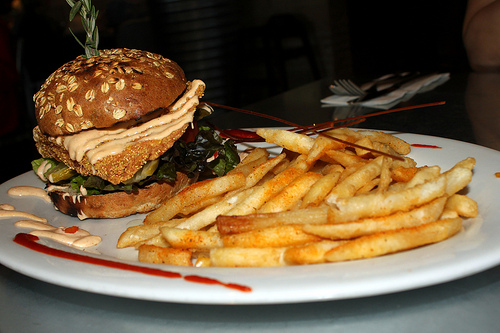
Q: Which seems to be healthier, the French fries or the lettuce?
A: The lettuce is healthier than the French fries.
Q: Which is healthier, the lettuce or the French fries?
A: The lettuce is healthier than the French fries.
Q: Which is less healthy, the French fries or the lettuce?
A: The French fries is less healthy than the lettuce.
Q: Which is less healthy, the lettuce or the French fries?
A: The French fries is less healthy than the lettuce.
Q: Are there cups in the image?
A: No, there are no cups.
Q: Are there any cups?
A: No, there are no cups.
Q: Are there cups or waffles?
A: No, there are no cups or waffles.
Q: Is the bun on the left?
A: Yes, the bun is on the left of the image.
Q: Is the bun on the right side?
A: No, the bun is on the left of the image.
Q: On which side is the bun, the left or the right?
A: The bun is on the left of the image.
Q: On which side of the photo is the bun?
A: The bun is on the left of the image.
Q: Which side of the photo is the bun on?
A: The bun is on the left of the image.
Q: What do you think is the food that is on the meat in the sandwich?
A: The food is a bun.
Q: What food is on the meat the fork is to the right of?
A: The food is a bun.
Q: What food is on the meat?
A: The food is a bun.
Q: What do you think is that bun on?
A: The bun is on the meat.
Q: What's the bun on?
A: The bun is on the meat.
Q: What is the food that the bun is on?
A: The food is meat.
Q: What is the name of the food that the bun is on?
A: The food is meat.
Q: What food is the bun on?
A: The bun is on the meat.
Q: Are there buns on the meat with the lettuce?
A: Yes, there is a bun on the meat.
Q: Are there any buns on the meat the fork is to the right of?
A: Yes, there is a bun on the meat.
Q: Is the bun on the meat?
A: Yes, the bun is on the meat.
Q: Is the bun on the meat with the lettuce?
A: Yes, the bun is on the meat.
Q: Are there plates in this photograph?
A: Yes, there is a plate.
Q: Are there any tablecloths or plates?
A: Yes, there is a plate.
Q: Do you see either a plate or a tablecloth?
A: Yes, there is a plate.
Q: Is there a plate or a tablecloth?
A: Yes, there is a plate.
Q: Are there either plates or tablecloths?
A: Yes, there is a plate.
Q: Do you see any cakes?
A: No, there are no cakes.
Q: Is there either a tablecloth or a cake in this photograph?
A: No, there are no cakes or tablecloths.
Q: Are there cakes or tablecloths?
A: No, there are no cakes or tablecloths.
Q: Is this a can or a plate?
A: This is a plate.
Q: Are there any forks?
A: Yes, there is a fork.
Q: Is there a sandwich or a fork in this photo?
A: Yes, there is a fork.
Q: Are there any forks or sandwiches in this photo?
A: Yes, there is a fork.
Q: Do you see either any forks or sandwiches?
A: Yes, there is a fork.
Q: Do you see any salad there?
A: No, there is no salad.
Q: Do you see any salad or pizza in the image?
A: No, there are no salad or pizzas.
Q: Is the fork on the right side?
A: Yes, the fork is on the right of the image.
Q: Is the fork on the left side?
A: No, the fork is on the right of the image.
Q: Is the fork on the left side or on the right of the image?
A: The fork is on the right of the image.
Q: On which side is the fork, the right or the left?
A: The fork is on the right of the image.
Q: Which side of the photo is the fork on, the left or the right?
A: The fork is on the right of the image.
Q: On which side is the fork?
A: The fork is on the right of the image.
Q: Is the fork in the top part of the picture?
A: Yes, the fork is in the top of the image.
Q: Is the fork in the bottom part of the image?
A: No, the fork is in the top of the image.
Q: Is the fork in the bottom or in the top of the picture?
A: The fork is in the top of the image.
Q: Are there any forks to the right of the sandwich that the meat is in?
A: Yes, there is a fork to the right of the sandwich.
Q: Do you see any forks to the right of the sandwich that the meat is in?
A: Yes, there is a fork to the right of the sandwich.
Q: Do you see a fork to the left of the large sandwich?
A: No, the fork is to the right of the sandwich.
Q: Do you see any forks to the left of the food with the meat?
A: No, the fork is to the right of the sandwich.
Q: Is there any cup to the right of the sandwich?
A: No, there is a fork to the right of the sandwich.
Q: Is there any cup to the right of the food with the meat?
A: No, there is a fork to the right of the sandwich.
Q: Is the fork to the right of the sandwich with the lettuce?
A: Yes, the fork is to the right of the sandwich.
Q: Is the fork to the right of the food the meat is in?
A: Yes, the fork is to the right of the sandwich.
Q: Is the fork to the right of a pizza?
A: No, the fork is to the right of the sandwich.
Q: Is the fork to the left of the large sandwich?
A: No, the fork is to the right of the sandwich.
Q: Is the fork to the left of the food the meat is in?
A: No, the fork is to the right of the sandwich.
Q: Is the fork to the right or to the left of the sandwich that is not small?
A: The fork is to the right of the sandwich.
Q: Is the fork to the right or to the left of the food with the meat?
A: The fork is to the right of the sandwich.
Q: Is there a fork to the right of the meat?
A: Yes, there is a fork to the right of the meat.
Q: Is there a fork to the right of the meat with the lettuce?
A: Yes, there is a fork to the right of the meat.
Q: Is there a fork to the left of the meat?
A: No, the fork is to the right of the meat.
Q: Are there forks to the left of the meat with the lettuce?
A: No, the fork is to the right of the meat.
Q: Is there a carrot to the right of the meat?
A: No, there is a fork to the right of the meat.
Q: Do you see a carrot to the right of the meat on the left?
A: No, there is a fork to the right of the meat.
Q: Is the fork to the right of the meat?
A: Yes, the fork is to the right of the meat.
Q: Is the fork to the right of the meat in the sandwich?
A: Yes, the fork is to the right of the meat.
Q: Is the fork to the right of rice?
A: No, the fork is to the right of the meat.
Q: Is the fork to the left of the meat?
A: No, the fork is to the right of the meat.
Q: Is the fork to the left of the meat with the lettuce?
A: No, the fork is to the right of the meat.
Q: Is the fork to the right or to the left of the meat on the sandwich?
A: The fork is to the right of the meat.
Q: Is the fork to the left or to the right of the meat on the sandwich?
A: The fork is to the right of the meat.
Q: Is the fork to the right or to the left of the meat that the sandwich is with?
A: The fork is to the right of the meat.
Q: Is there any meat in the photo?
A: Yes, there is meat.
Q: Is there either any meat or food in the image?
A: Yes, there is meat.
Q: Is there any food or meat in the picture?
A: Yes, there is meat.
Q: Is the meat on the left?
A: Yes, the meat is on the left of the image.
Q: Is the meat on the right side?
A: No, the meat is on the left of the image.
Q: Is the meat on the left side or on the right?
A: The meat is on the left of the image.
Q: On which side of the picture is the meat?
A: The meat is on the left of the image.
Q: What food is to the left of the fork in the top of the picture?
A: The food is meat.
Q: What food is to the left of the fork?
A: The food is meat.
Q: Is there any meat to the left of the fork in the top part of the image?
A: Yes, there is meat to the left of the fork.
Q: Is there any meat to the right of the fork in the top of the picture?
A: No, the meat is to the left of the fork.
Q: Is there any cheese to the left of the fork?
A: No, there is meat to the left of the fork.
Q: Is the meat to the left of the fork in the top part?
A: Yes, the meat is to the left of the fork.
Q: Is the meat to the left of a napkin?
A: No, the meat is to the left of the fork.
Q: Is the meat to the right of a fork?
A: No, the meat is to the left of a fork.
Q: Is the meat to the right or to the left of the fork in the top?
A: The meat is to the left of the fork.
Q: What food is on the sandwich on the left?
A: The food is meat.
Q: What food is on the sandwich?
A: The food is meat.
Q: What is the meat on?
A: The meat is on the sandwich.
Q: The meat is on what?
A: The meat is on the sandwich.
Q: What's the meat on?
A: The meat is on the sandwich.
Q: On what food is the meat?
A: The meat is on the sandwich.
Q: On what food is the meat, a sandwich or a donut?
A: The meat is on a sandwich.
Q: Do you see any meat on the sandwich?
A: Yes, there is meat on the sandwich.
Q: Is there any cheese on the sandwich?
A: No, there is meat on the sandwich.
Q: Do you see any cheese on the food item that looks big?
A: No, there is meat on the sandwich.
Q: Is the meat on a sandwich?
A: Yes, the meat is on a sandwich.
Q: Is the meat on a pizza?
A: No, the meat is on a sandwich.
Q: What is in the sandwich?
A: The meat is in the sandwich.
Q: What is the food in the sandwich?
A: The food is meat.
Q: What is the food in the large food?
A: The food is meat.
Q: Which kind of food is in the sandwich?
A: The food is meat.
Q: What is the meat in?
A: The meat is in the sandwich.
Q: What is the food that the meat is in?
A: The food is a sandwich.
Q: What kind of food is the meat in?
A: The meat is in the sandwich.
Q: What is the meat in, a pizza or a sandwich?
A: The meat is in a sandwich.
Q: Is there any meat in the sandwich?
A: Yes, there is meat in the sandwich.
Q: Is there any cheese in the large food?
A: No, there is meat in the sandwich.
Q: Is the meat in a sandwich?
A: Yes, the meat is in a sandwich.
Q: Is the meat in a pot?
A: No, the meat is in a sandwich.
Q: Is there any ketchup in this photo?
A: Yes, there is ketchup.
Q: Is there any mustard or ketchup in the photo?
A: Yes, there is ketchup.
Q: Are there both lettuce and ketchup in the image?
A: Yes, there are both ketchup and lettuce.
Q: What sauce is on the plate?
A: The sauce is ketchup.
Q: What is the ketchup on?
A: The ketchup is on the plate.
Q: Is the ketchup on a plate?
A: Yes, the ketchup is on a plate.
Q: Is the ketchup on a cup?
A: No, the ketchup is on a plate.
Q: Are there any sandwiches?
A: Yes, there is a sandwich.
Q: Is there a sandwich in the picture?
A: Yes, there is a sandwich.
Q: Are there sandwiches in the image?
A: Yes, there is a sandwich.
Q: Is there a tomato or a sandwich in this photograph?
A: Yes, there is a sandwich.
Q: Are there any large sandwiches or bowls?
A: Yes, there is a large sandwich.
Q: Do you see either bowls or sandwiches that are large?
A: Yes, the sandwich is large.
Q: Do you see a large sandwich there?
A: Yes, there is a large sandwich.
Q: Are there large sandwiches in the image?
A: Yes, there is a large sandwich.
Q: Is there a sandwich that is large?
A: Yes, there is a sandwich that is large.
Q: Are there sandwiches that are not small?
A: Yes, there is a large sandwich.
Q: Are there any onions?
A: No, there are no onions.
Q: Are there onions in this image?
A: No, there are no onions.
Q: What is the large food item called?
A: The food item is a sandwich.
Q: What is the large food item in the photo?
A: The food item is a sandwich.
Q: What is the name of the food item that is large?
A: The food item is a sandwich.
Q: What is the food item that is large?
A: The food item is a sandwich.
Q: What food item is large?
A: The food item is a sandwich.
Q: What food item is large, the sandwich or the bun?
A: The sandwich is large.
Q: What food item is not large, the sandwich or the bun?
A: The bun is not large.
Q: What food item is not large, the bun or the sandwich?
A: The bun is not large.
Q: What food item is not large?
A: The food item is a bun.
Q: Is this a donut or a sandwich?
A: This is a sandwich.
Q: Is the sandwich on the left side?
A: Yes, the sandwich is on the left of the image.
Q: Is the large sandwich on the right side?
A: No, the sandwich is on the left of the image.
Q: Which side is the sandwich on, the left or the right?
A: The sandwich is on the left of the image.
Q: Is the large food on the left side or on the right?
A: The sandwich is on the left of the image.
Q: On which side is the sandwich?
A: The sandwich is on the left of the image.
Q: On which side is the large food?
A: The sandwich is on the left of the image.